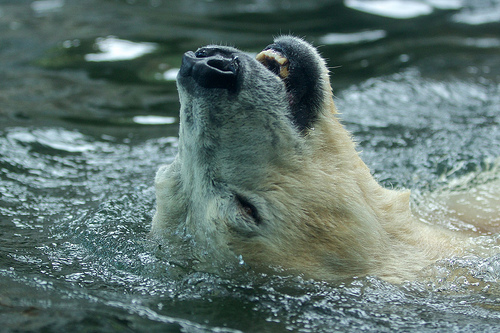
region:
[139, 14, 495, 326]
this is a bear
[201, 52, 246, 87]
a nostril of a bear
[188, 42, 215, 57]
a nostril of a bear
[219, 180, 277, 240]
an eye of a bear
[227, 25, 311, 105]
a mouth of a bear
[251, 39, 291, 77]
white teeth of a bear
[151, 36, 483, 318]
Bear head in the water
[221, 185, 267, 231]
bear eye is closed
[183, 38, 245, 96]
black nose on a bear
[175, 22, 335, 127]
bear with its mouth opened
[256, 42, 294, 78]
teeth on a bear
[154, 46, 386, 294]
bear head submerged in watet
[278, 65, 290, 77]
yellowed polar bear tooth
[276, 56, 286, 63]
yellowed polar bear tooth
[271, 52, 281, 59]
yellowed polar bear tooth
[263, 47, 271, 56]
yellowed polar bear tooth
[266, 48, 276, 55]
yellowed polar bear tooth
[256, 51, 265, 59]
yellowed polar bear tooth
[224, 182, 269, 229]
closed polar bear eye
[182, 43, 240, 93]
black polar bear nose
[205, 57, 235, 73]
black polar bear nostril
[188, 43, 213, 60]
black polar bear nostril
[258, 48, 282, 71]
the polar bears teeth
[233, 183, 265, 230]
right eye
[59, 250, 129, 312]
the water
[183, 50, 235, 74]
the polar bears nose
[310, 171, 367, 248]
the fur is white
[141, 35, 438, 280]
the polar bear is in the water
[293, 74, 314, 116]
lips are black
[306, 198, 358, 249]
fur is white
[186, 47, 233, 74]
the nose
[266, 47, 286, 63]
teeth are yellow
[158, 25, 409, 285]
A polar bears head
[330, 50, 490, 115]
Wake from a polar bear swimming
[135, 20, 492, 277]
A polar bear laying on his back in water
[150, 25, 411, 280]
A polar bear with his mouth open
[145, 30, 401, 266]
A polar bear floating in the water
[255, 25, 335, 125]
The bottom jaw of a polar bear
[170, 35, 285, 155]
A polar bear nose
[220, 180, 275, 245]
A polar bears eye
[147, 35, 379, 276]
A polar bear looking up at the sky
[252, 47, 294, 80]
A polar bears bottom teeth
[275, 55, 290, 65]
yellowed polar bear tooth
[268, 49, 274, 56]
yellowed polar bear tooth